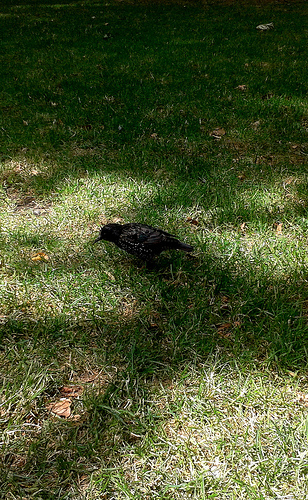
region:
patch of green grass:
[120, 75, 190, 134]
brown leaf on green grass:
[44, 393, 81, 422]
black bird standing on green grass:
[83, 217, 203, 273]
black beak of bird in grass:
[86, 236, 104, 246]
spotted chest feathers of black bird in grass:
[118, 236, 153, 256]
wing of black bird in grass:
[124, 224, 171, 248]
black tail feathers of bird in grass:
[173, 237, 195, 255]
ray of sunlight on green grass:
[143, 373, 287, 494]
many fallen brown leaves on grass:
[214, 49, 297, 161]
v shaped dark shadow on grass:
[2, 302, 188, 490]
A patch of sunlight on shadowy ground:
[113, 357, 303, 499]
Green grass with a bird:
[11, 15, 304, 480]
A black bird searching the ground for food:
[87, 220, 197, 270]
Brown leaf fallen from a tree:
[44, 382, 86, 424]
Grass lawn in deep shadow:
[5, 4, 304, 70]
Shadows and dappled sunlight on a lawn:
[4, 119, 297, 494]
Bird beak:
[91, 233, 105, 249]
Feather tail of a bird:
[166, 233, 196, 252]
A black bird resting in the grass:
[85, 214, 200, 279]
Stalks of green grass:
[189, 351, 297, 399]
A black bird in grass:
[97, 212, 178, 267]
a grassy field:
[8, 7, 297, 497]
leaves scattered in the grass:
[65, 25, 289, 218]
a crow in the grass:
[86, 205, 201, 294]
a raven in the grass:
[83, 212, 193, 276]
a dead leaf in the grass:
[244, 22, 277, 42]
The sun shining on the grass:
[5, 167, 305, 490]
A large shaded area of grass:
[3, 17, 304, 181]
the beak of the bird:
[88, 236, 103, 246]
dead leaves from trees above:
[5, 12, 306, 493]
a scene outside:
[3, 2, 305, 494]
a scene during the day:
[4, 3, 304, 495]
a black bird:
[84, 208, 231, 282]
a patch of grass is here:
[7, 37, 300, 494]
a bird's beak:
[75, 217, 99, 250]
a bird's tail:
[165, 224, 204, 268]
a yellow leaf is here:
[22, 236, 67, 269]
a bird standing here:
[79, 211, 204, 278]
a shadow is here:
[0, 0, 303, 214]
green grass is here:
[3, 219, 304, 495]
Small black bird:
[72, 216, 197, 275]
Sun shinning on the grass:
[8, 157, 122, 242]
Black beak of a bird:
[85, 232, 108, 248]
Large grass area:
[26, 99, 277, 200]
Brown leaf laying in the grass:
[39, 388, 91, 433]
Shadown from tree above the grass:
[83, 271, 300, 387]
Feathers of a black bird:
[117, 221, 179, 261]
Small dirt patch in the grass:
[5, 182, 60, 226]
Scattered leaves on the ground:
[170, 64, 291, 182]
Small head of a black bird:
[82, 220, 129, 247]